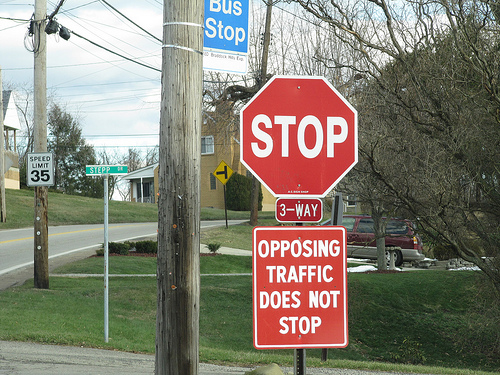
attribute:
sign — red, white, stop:
[246, 72, 357, 202]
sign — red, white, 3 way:
[274, 202, 327, 227]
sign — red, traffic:
[244, 225, 351, 352]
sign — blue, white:
[203, 4, 249, 52]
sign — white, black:
[31, 150, 58, 190]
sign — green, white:
[84, 159, 129, 174]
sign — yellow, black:
[211, 156, 230, 184]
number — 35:
[28, 169, 54, 181]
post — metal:
[95, 186, 123, 345]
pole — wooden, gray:
[167, 69, 198, 333]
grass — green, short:
[38, 305, 73, 328]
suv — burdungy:
[345, 214, 416, 267]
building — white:
[4, 87, 17, 187]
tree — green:
[418, 82, 485, 128]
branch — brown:
[411, 91, 430, 115]